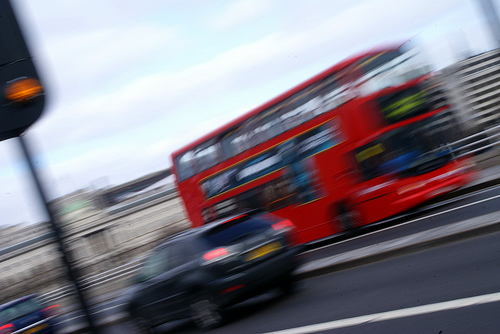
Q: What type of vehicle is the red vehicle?
A: Bus.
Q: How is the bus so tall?
A: The bus is a double-decker.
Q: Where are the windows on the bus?
A: On the sides and top of the bus.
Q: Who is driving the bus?
A: The bus driver.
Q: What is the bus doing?
A: Driving down the road.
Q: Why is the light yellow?
A: Telling drivers to slow down.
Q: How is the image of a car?
A: Blurry.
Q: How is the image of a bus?
A: Blurry.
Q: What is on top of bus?
A: Seats.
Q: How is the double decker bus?
A: Red.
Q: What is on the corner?
A: A traffic light.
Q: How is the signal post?
A: Black metal.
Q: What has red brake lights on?
A: Dark green cross-over.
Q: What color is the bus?
A: Red.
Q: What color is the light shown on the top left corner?
A: Yellow.